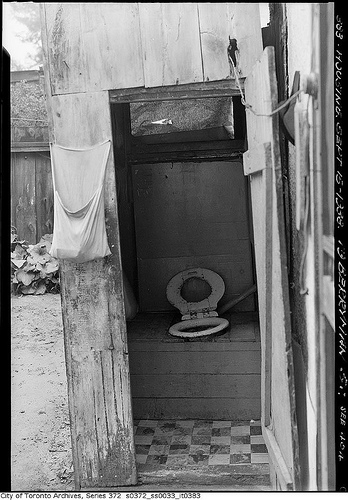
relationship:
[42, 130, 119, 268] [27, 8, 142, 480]
white cloth hanging from wall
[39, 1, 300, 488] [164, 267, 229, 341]
outhouse with toilet seat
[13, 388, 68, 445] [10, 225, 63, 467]
dirt near shed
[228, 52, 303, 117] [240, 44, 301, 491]
string on door